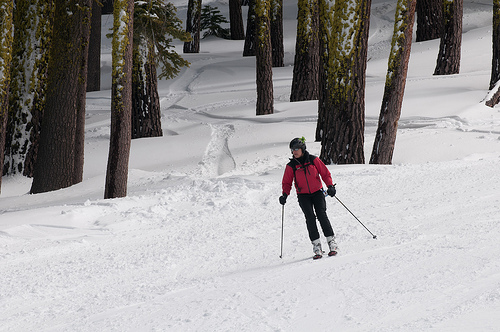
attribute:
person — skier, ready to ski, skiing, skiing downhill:
[280, 137, 339, 257]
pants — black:
[296, 190, 335, 240]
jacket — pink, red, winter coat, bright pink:
[282, 155, 333, 194]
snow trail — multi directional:
[160, 58, 237, 177]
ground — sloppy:
[1, 1, 498, 331]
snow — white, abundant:
[0, 2, 497, 328]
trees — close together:
[0, 1, 498, 198]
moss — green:
[327, 1, 357, 102]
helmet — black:
[290, 138, 305, 150]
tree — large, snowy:
[319, 0, 368, 161]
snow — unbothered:
[232, 121, 326, 169]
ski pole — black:
[278, 202, 285, 255]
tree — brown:
[368, 1, 418, 164]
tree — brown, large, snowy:
[32, 0, 89, 194]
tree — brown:
[290, 0, 320, 101]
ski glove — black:
[279, 193, 287, 204]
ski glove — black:
[329, 183, 337, 197]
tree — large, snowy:
[131, 13, 163, 139]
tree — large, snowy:
[3, 2, 55, 178]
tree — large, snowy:
[416, 1, 447, 40]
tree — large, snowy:
[434, 0, 462, 75]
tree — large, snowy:
[184, 0, 201, 54]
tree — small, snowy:
[228, 0, 245, 40]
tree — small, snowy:
[315, 0, 337, 141]